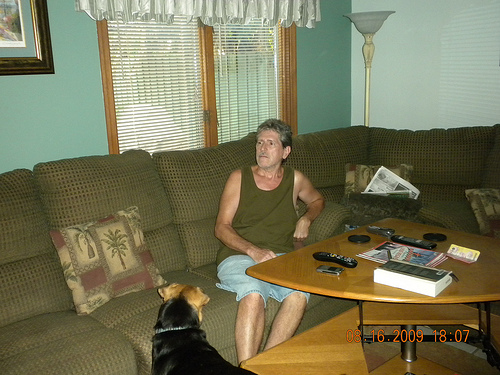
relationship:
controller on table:
[297, 241, 378, 282] [241, 212, 498, 372]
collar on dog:
[149, 322, 196, 334] [148, 282, 265, 374]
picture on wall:
[4, 2, 60, 79] [1, 6, 499, 173]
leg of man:
[235, 291, 267, 367] [228, 121, 329, 357]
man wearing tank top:
[215, 116, 313, 363] [214, 165, 296, 266]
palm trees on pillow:
[57, 210, 162, 310] [48, 205, 168, 312]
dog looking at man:
[150, 273, 244, 371] [215, 116, 313, 363]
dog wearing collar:
[150, 273, 244, 371] [143, 318, 195, 335]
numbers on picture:
[344, 324, 476, 347] [30, 14, 460, 360]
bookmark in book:
[447, 270, 460, 285] [370, 258, 458, 297]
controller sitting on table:
[312, 251, 357, 268] [243, 172, 498, 302]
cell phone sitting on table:
[313, 261, 348, 278] [216, 209, 498, 324]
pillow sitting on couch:
[52, 202, 167, 321] [0, 122, 497, 373]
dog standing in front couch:
[150, 273, 244, 371] [0, 122, 497, 373]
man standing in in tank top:
[215, 116, 313, 363] [231, 160, 306, 250]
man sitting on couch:
[215, 116, 313, 363] [0, 122, 497, 373]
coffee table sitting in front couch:
[241, 217, 498, 372] [0, 122, 497, 373]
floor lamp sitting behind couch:
[345, 9, 395, 123] [63, 112, 496, 316]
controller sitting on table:
[312, 251, 357, 268] [206, 215, 488, 341]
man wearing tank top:
[215, 116, 313, 363] [224, 161, 297, 258]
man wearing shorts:
[215, 116, 313, 363] [217, 253, 298, 300]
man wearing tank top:
[215, 116, 313, 363] [217, 162, 297, 254]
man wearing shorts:
[215, 116, 313, 363] [222, 255, 302, 294]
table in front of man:
[248, 213, 498, 321] [218, 103, 336, 361]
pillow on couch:
[52, 202, 167, 321] [0, 122, 497, 373]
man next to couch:
[215, 116, 313, 363] [0, 122, 497, 373]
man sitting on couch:
[217, 116, 314, 340] [0, 122, 497, 373]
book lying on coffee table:
[370, 258, 458, 297] [241, 217, 498, 372]